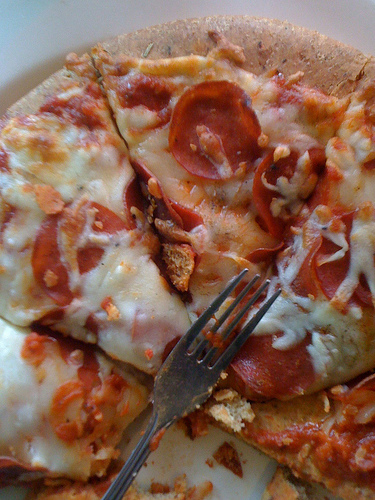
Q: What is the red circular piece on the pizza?
A: Pepperoni.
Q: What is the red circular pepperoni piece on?
A: Pizza.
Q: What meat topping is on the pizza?
A: Pepperoni.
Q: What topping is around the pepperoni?
A: Cheese.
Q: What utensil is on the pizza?
A: A fork.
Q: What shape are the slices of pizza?
A: Triangle.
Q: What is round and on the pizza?
A: Pepperoni.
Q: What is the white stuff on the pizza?
A: Cheese.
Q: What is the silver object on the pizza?
A: A fork.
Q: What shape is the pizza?
A: Round.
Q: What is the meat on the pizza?
A: Pepperoni.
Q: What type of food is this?
A: Pizza.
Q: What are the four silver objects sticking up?
A: Fork tines.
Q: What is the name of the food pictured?
A: Pizza.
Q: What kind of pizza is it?
A: Pepperoni.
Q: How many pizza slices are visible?
A: Five.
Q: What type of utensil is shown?
A: Fork.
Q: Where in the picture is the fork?
A: Bottom.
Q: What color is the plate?
A: White.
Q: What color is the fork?
A: Silver.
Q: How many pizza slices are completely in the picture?
A: One.